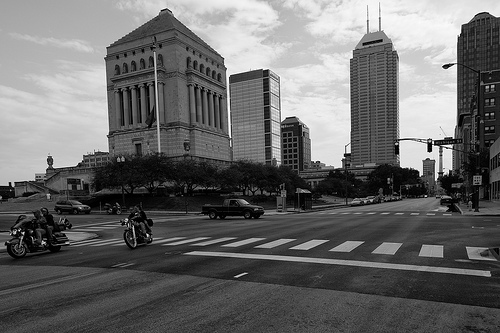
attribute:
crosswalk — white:
[70, 236, 499, 261]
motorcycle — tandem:
[6, 227, 71, 258]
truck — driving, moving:
[202, 197, 265, 219]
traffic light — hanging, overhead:
[394, 141, 401, 155]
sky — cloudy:
[1, 0, 499, 175]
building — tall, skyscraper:
[350, 32, 399, 175]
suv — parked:
[54, 199, 92, 213]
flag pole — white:
[152, 44, 162, 158]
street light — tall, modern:
[442, 62, 480, 213]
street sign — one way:
[473, 174, 483, 187]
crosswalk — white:
[284, 210, 462, 216]